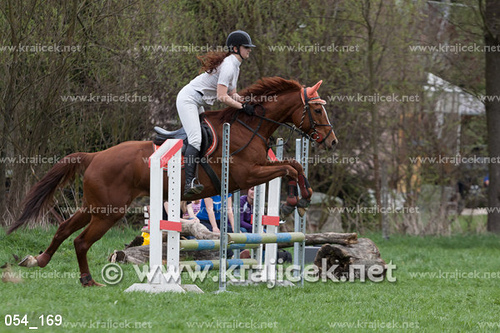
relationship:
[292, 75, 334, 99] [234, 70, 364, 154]
cover on horse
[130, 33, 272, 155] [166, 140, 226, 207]
girl in boots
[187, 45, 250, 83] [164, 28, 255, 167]
hair on girl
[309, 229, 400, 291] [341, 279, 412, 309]
log on ground